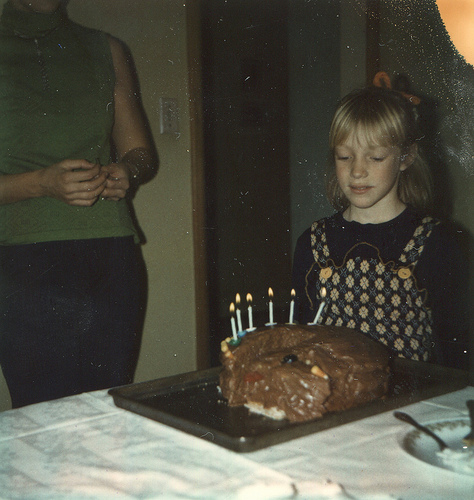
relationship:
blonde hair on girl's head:
[330, 86, 431, 213] [319, 82, 432, 222]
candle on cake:
[308, 287, 330, 326] [217, 322, 395, 423]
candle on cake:
[285, 287, 298, 325] [217, 322, 395, 423]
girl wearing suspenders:
[279, 82, 467, 367] [309, 215, 438, 284]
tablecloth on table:
[84, 453, 178, 499] [0, 341, 473, 498]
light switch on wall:
[157, 93, 182, 137] [77, 2, 209, 373]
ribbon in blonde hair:
[374, 69, 418, 110] [325, 86, 439, 214]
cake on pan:
[185, 259, 419, 435] [107, 356, 469, 454]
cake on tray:
[217, 322, 395, 423] [108, 356, 469, 452]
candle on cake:
[283, 282, 299, 325] [217, 322, 395, 423]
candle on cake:
[263, 283, 278, 326] [217, 322, 395, 423]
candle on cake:
[244, 289, 260, 329] [217, 322, 395, 423]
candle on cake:
[234, 293, 245, 336] [217, 322, 395, 423]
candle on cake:
[228, 302, 241, 346] [217, 322, 395, 423]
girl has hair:
[279, 82, 467, 367] [322, 82, 443, 214]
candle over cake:
[228, 302, 241, 346] [217, 322, 395, 423]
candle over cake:
[234, 293, 245, 336] [217, 322, 395, 423]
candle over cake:
[244, 292, 257, 332] [217, 322, 395, 423]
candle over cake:
[263, 285, 277, 326] [217, 322, 395, 423]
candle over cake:
[285, 287, 298, 325] [217, 322, 395, 423]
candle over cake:
[308, 287, 330, 326] [217, 322, 395, 423]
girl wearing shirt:
[290, 82, 473, 377] [0, 18, 150, 248]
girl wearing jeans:
[290, 82, 473, 377] [2, 232, 149, 410]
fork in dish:
[391, 409, 447, 453] [393, 410, 472, 488]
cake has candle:
[217, 322, 395, 423] [309, 284, 329, 327]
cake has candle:
[217, 322, 395, 423] [283, 283, 301, 325]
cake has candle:
[217, 322, 395, 423] [264, 285, 278, 328]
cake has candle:
[217, 322, 395, 423] [245, 286, 257, 332]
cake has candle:
[217, 322, 395, 423] [231, 289, 246, 335]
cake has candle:
[217, 322, 395, 423] [224, 301, 242, 346]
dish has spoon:
[393, 410, 473, 481] [388, 398, 457, 455]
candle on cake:
[263, 285, 277, 326] [208, 302, 398, 401]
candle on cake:
[222, 285, 246, 336] [200, 312, 405, 421]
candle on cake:
[222, 302, 246, 345] [216, 316, 393, 410]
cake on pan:
[217, 322, 395, 423] [105, 338, 469, 458]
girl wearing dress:
[279, 82, 467, 367] [309, 207, 441, 362]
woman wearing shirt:
[1, 0, 158, 406] [0, 16, 134, 227]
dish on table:
[393, 410, 473, 481] [31, 378, 459, 489]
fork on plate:
[392, 403, 441, 452] [400, 425, 429, 468]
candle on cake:
[228, 302, 241, 346] [221, 316, 408, 420]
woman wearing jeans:
[1, 0, 158, 406] [2, 232, 147, 406]